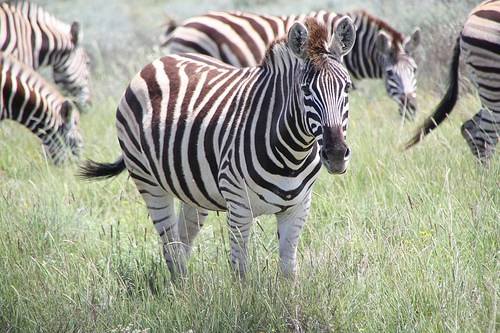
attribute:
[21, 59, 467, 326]
grass — long , green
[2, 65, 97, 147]
zebra — white, black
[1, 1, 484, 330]
grass — green, tan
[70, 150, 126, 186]
zebra tail — black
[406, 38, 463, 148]
tail — black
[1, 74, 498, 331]
grass — long, green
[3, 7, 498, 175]
zebras — five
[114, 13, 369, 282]
zebra — one, looking at the camera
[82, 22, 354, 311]
zebra — black, white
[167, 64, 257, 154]
stripes — black, white